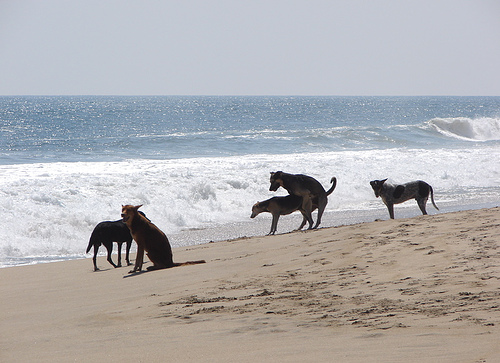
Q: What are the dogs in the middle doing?
A: Making love.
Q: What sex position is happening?
A: Doggy style.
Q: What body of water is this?
A: The ocean.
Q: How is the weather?
A: Clear.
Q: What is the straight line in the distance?
A: Horizon.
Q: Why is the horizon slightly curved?
A: It's the curvature of the Earth.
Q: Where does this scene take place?
A: The beach.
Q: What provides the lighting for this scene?
A: The sun.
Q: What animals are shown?
A: Dogs.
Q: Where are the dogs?
A: At the beach.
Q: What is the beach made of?
A: Sand.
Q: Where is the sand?
A: On the beach.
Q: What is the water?
A: The ocean.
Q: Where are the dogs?
A: On the sand.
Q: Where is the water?
A: Behind the dogs.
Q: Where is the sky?
A: Above the water.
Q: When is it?
A: Day time.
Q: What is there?
A: Dogs.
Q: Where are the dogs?
A: On the beach.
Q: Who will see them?
A: People.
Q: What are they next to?
A: Water.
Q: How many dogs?
A: 5.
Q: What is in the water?
A: Waves.